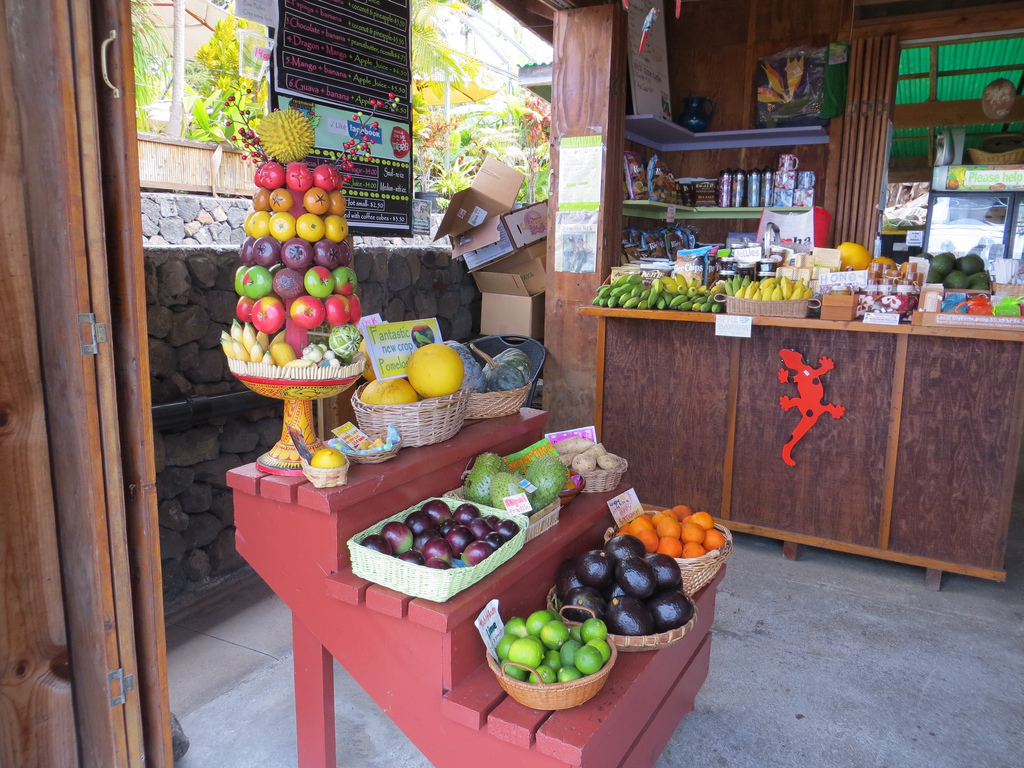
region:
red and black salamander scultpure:
[764, 341, 850, 466]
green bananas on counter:
[593, 262, 726, 316]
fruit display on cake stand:
[224, 98, 370, 485]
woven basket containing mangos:
[334, 487, 532, 602]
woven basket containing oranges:
[610, 497, 731, 603]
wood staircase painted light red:
[235, 392, 717, 765]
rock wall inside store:
[141, 186, 500, 614]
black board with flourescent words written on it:
[267, 0, 419, 239]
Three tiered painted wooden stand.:
[241, 366, 741, 766]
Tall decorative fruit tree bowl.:
[229, 136, 370, 494]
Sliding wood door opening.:
[13, 10, 185, 766]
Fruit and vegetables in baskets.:
[364, 385, 731, 721]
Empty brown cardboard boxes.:
[437, 141, 554, 360]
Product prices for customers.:
[273, 5, 442, 237]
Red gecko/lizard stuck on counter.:
[748, 337, 857, 489]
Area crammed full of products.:
[630, 40, 1022, 331]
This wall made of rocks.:
[165, 264, 236, 613]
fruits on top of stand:
[228, 382, 747, 762]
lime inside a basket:
[473, 603, 625, 711]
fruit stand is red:
[221, 392, 719, 765]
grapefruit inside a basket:
[351, 322, 475, 449]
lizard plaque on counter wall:
[767, 341, 851, 472]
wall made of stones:
[135, 181, 540, 635]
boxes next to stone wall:
[429, 142, 553, 409]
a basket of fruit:
[353, 474, 537, 604]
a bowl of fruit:
[475, 591, 618, 712]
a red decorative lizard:
[753, 318, 853, 484]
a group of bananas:
[714, 252, 807, 311]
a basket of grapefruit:
[358, 328, 483, 446]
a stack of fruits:
[221, 129, 373, 398]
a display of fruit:
[215, 410, 709, 759]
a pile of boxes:
[439, 135, 548, 338]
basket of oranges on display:
[612, 495, 729, 604]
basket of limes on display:
[477, 604, 614, 707]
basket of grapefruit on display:
[362, 347, 465, 446]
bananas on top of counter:
[594, 246, 819, 349]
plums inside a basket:
[373, 496, 525, 582]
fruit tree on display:
[230, 124, 360, 476]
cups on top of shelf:
[714, 151, 820, 210]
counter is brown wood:
[585, 296, 1019, 588]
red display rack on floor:
[223, 375, 732, 762]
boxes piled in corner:
[424, 157, 562, 354]